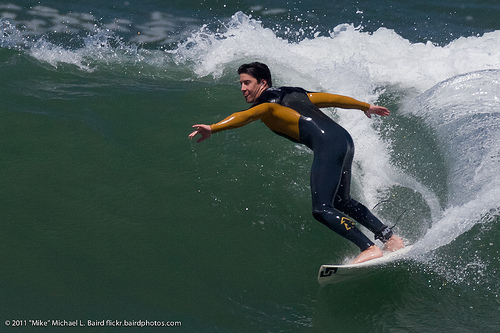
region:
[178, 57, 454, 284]
surfer creating a curved trail behind board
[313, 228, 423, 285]
bare feet on a white surfboard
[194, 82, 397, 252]
black wetsuit with brown panels on sleeves and torso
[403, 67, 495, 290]
water forming a curve and drops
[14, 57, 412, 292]
surfer facing dark green water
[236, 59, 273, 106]
tongue sticking out of focused face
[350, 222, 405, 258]
The feet of the surfer.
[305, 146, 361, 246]
The left leg of the surfer.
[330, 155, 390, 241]
The right leg of the surfer.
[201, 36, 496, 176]
The white bubbles of the wave.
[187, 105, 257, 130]
The surfer's left arm.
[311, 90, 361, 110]
The surfer's right arm.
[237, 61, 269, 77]
The short black hair of the surfer.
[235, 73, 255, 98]
The face of the surfer.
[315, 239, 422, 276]
The surfboard the surfer is riding on.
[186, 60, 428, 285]
a man riding a surf board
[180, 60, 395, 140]
a man with his arms stretched out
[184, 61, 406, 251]
a man wearing a wet suit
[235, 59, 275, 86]
a man with dark hair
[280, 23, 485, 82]
a white wave in the water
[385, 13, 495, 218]
a white wave in the ocean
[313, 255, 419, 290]
a white surf board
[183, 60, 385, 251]
a man wearing a brown and black wetsuit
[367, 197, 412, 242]
a rope attached to a man's ankle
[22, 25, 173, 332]
a large body of water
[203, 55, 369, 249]
surfer in black and gold wet suit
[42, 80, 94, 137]
white and green ocean waves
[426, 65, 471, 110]
white and green ocean waves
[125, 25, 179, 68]
white and green ocean waves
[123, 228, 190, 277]
white and green ocean waves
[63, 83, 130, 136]
white and green ocean waves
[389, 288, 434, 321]
white and green ocean waves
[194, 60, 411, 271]
A MAN IS SURFING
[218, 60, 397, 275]
a man on a surfboard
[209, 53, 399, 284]
a man wearing a wetsuit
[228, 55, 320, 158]
a man wearing a wetsuit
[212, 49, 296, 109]
head of a man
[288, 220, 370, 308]
front of a board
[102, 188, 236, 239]
water next to the man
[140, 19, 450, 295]
a person is a surfer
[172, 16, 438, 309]
a person is surfing a wave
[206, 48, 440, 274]
a person on a surfbaord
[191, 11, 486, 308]
a person standing on a surfboard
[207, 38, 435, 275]
a person is balancing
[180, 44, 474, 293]
a person wearing a wetsuit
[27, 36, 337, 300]
a body of water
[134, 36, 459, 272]
person in the water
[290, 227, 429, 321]
board under the man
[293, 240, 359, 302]
front of the board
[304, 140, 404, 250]
legs of the person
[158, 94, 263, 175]
arm of the person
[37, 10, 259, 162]
wave forming in the water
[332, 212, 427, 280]
bare feet of the man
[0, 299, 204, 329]
words in bottom left corner